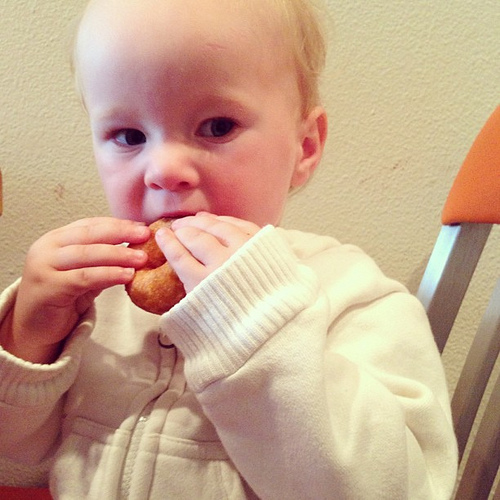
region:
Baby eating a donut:
[0, 0, 476, 496]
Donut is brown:
[118, 212, 213, 317]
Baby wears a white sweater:
[4, 1, 481, 498]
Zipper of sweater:
[104, 329, 179, 496]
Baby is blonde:
[8, 2, 395, 347]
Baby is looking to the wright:
[6, 1, 439, 353]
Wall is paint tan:
[334, 9, 493, 136]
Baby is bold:
[11, 0, 376, 292]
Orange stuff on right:
[431, 97, 498, 241]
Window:
[416, 216, 473, 307]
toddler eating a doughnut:
[59, 6, 379, 487]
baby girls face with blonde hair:
[49, 12, 361, 277]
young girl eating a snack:
[29, 5, 495, 470]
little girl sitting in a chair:
[48, 9, 495, 485]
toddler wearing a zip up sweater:
[26, 15, 428, 487]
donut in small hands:
[112, 187, 247, 324]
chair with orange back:
[376, 82, 498, 433]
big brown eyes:
[80, 93, 280, 195]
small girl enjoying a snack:
[20, 3, 352, 370]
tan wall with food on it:
[28, 10, 491, 413]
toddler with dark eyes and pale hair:
[45, 25, 345, 205]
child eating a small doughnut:
[85, 106, 280, 316]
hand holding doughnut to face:
[92, 205, 207, 312]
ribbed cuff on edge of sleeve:
[145, 216, 396, 482]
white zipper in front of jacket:
[101, 320, 183, 495]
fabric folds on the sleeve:
[310, 296, 456, 486]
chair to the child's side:
[97, 50, 494, 435]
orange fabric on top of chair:
[405, 85, 495, 236]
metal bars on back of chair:
[410, 221, 495, 492]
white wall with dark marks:
[343, 92, 415, 218]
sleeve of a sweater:
[210, 276, 280, 353]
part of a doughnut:
[140, 282, 172, 308]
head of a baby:
[133, 31, 198, 89]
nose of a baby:
[138, 157, 194, 184]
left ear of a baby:
[296, 103, 328, 173]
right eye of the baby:
[111, 112, 155, 145]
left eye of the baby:
[203, 115, 231, 140]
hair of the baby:
[278, 12, 330, 94]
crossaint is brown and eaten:
[125, 216, 227, 317]